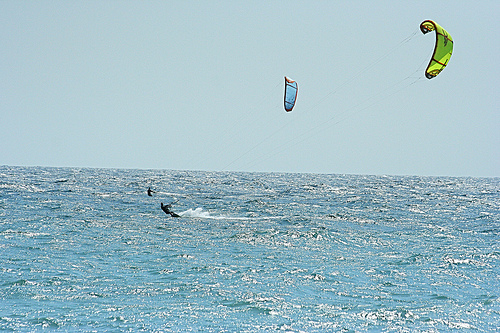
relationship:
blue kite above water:
[280, 72, 300, 114] [0, 164, 499, 331]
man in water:
[160, 202, 180, 217] [0, 164, 499, 331]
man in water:
[150, 197, 186, 227] [270, 251, 385, 317]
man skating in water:
[137, 175, 227, 244] [205, 192, 495, 331]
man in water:
[147, 187, 156, 196] [0, 164, 499, 331]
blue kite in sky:
[283, 76, 299, 112] [3, 3, 493, 180]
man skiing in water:
[147, 187, 156, 196] [2, 164, 393, 325]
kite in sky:
[411, 10, 456, 88] [416, 13, 459, 85]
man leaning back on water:
[160, 202, 180, 217] [153, 221, 312, 271]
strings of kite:
[408, 32, 417, 46] [411, 10, 456, 88]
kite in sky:
[411, 10, 456, 88] [4, 3, 396, 77]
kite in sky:
[411, 10, 456, 88] [4, 0, 495, 200]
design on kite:
[434, 25, 448, 48] [411, 10, 456, 88]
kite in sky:
[411, 10, 456, 88] [3, 3, 493, 180]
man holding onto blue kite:
[160, 202, 180, 217] [283, 76, 299, 112]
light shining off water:
[185, 256, 282, 310] [0, 164, 499, 331]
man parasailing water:
[160, 202, 180, 217] [0, 164, 499, 331]